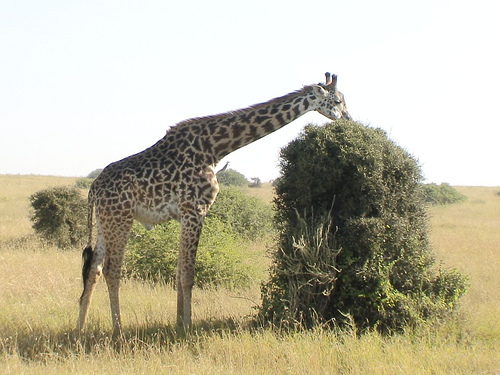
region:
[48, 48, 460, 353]
giraffe out near tree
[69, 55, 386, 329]
tall giraffe out near tree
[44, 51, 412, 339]
adult giraffe out near tree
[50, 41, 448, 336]
attractive giraffe out near tree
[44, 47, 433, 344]
big giraffe out near tree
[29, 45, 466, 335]
healthy giraffe out near tree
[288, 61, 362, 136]
head of a giraffe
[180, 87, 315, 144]
neck of a giraffe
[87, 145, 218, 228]
body of a giraffe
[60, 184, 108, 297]
tail of a giraffe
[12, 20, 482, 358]
The giraffe is standing up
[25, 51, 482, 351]
The giraffe is walking around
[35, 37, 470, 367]
The giraffe is out in daytime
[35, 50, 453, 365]
The giraffe is eating something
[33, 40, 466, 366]
The giraffe is looking for food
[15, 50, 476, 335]
The giraffe is in a field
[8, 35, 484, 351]
A giraffes is out in the open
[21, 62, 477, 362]
A giraffe is standing in tall grass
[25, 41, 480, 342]
The giraffe is watching for danger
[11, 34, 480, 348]
The giraffe found something on a bush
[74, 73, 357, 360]
a giraffe in a grassy field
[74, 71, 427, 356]
a giraffe grazing from a bush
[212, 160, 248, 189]
a giraffe next to a bush in the background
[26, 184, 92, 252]
a bush in the grass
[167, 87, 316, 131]
the giraffe has a brown mane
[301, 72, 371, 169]
the giraffe is looking at the bush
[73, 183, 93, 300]
the giraffe's tail has black hair at the end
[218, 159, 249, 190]
a bush in front of a giraffe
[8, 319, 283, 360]
a shadow on the grass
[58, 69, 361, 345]
a giraffe in a grassland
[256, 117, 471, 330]
A tall bush a giraffe is eating from.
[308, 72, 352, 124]
The head of a giraffe eating out of a bush.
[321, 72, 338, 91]
Two black, brown and white horns on a giraffes head.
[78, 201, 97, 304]
Long brown, white and black giraffe tail.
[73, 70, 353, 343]
Tall brown and white spotted giraffe.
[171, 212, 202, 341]
Two front brown and white legs of a giraffe.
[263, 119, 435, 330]
A tall green bush a giraffe is eating on.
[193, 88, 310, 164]
Brown and white spotted neck on a giraffe between it's head and body.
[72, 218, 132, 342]
Back two spotted legs of a giraffe.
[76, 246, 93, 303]
Black hairy end of a giraffe tail.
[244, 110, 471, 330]
A large green bush.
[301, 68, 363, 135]
A horned giraffe head.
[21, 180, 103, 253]
A small green bush in a field.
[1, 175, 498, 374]
A field full of dry grass.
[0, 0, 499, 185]
A section of hazy gray sky.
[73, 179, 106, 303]
A tail on a giraffe.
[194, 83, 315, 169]
A long giraffe neck.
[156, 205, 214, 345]
front legs of a giraffe.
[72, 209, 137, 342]
Hind legs of a giraffe.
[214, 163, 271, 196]
a large leafy green tree.